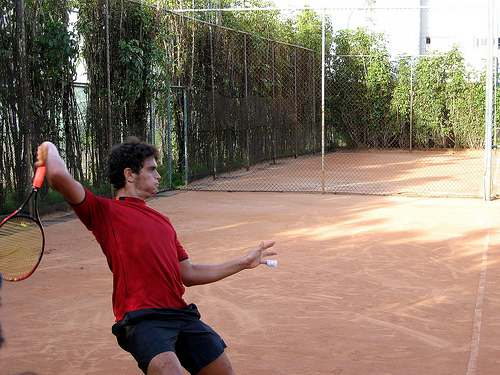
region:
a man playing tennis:
[1, 135, 278, 373]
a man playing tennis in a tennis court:
[1, 0, 498, 370]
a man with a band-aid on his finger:
[263, 255, 279, 269]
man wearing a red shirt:
[74, 188, 188, 307]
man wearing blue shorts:
[113, 303, 223, 370]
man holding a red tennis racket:
[0, 139, 65, 294]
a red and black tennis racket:
[0, 160, 47, 280]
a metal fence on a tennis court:
[167, 0, 497, 195]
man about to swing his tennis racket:
[2, 128, 282, 309]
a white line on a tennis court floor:
[466, 203, 498, 374]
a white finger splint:
[265, 258, 283, 268]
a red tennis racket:
[0, 159, 55, 285]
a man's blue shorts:
[111, 305, 229, 371]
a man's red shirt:
[71, 186, 199, 323]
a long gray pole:
[313, 0, 335, 192]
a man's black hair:
[102, 138, 159, 195]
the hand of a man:
[33, 136, 57, 168]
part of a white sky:
[427, 10, 496, 34]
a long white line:
[457, 200, 497, 373]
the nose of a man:
[151, 168, 164, 181]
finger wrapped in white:
[263, 258, 276, 271]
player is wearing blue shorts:
[141, 317, 200, 350]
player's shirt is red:
[112, 219, 167, 289]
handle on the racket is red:
[34, 161, 58, 183]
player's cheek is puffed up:
[123, 176, 174, 206]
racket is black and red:
[29, 247, 44, 280]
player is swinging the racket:
[23, 143, 55, 192]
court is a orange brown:
[342, 283, 425, 365]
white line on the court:
[453, 320, 498, 358]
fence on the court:
[290, 121, 335, 192]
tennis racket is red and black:
[0, 161, 52, 285]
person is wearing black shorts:
[106, 301, 230, 373]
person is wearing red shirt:
[65, 179, 194, 324]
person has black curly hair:
[101, 130, 160, 190]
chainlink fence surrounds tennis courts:
[2, 67, 497, 222]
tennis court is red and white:
[1, 146, 499, 373]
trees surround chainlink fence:
[1, 0, 498, 214]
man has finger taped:
[261, 257, 282, 271]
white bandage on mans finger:
[263, 254, 288, 269]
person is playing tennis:
[0, 138, 280, 374]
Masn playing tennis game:
[1, 139, 288, 372]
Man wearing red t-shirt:
[83, 144, 190, 311]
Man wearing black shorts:
[109, 299, 221, 366]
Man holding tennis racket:
[0, 138, 272, 373]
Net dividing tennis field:
[174, 5, 486, 194]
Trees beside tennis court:
[6, 0, 338, 153]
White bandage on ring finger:
[266, 260, 279, 267]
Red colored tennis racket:
[0, 167, 47, 278]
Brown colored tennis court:
[7, 192, 499, 366]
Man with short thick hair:
[110, 134, 163, 199]